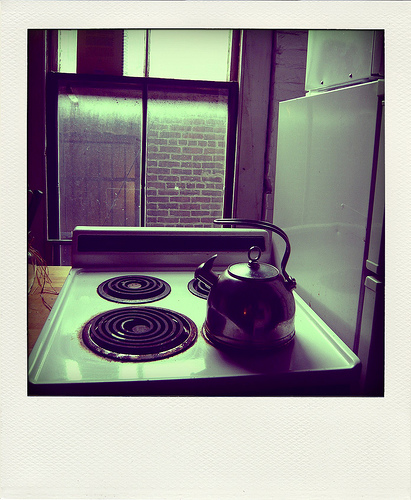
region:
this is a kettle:
[182, 196, 331, 366]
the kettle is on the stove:
[160, 174, 321, 347]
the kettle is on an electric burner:
[180, 194, 323, 367]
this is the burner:
[78, 296, 184, 368]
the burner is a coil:
[71, 299, 202, 362]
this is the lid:
[224, 232, 276, 280]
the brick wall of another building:
[149, 104, 230, 230]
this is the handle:
[205, 201, 305, 269]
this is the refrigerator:
[270, 73, 385, 316]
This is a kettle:
[189, 204, 322, 365]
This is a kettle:
[194, 210, 322, 402]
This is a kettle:
[185, 204, 323, 363]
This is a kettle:
[194, 210, 307, 360]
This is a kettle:
[199, 215, 317, 357]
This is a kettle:
[197, 217, 320, 364]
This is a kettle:
[199, 206, 319, 358]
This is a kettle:
[194, 211, 309, 354]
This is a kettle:
[191, 207, 313, 364]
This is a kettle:
[197, 213, 320, 367]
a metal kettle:
[192, 198, 308, 367]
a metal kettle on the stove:
[157, 214, 322, 394]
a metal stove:
[37, 206, 365, 377]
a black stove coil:
[74, 300, 210, 373]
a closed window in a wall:
[30, 24, 253, 258]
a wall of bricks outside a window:
[64, 90, 221, 222]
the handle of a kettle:
[218, 206, 305, 294]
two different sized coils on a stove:
[77, 271, 199, 398]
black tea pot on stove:
[187, 214, 286, 360]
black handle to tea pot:
[208, 206, 289, 239]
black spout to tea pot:
[191, 253, 220, 284]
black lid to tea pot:
[229, 242, 273, 284]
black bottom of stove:
[85, 297, 176, 360]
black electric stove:
[108, 266, 159, 302]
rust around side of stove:
[114, 354, 139, 362]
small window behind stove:
[57, 87, 238, 225]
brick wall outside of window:
[145, 116, 215, 221]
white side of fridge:
[260, 76, 375, 193]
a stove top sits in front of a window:
[33, 28, 355, 381]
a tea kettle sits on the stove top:
[179, 199, 312, 364]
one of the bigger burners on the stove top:
[77, 304, 200, 365]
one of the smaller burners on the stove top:
[95, 267, 172, 302]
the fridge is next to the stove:
[277, 77, 381, 406]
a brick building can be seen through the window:
[149, 105, 221, 225]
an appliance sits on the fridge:
[301, 32, 380, 87]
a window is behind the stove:
[36, 31, 246, 245]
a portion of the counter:
[26, 260, 73, 360]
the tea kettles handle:
[210, 202, 298, 278]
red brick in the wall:
[144, 152, 171, 161]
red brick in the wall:
[146, 164, 172, 172]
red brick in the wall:
[151, 172, 184, 180]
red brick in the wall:
[177, 171, 199, 182]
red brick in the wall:
[196, 171, 222, 182]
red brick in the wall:
[141, 177, 165, 190]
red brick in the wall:
[165, 179, 184, 189]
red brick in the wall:
[155, 187, 176, 197]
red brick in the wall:
[178, 187, 201, 195]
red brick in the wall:
[168, 194, 190, 203]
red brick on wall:
[147, 216, 158, 223]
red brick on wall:
[157, 218, 178, 223]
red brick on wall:
[181, 215, 200, 222]